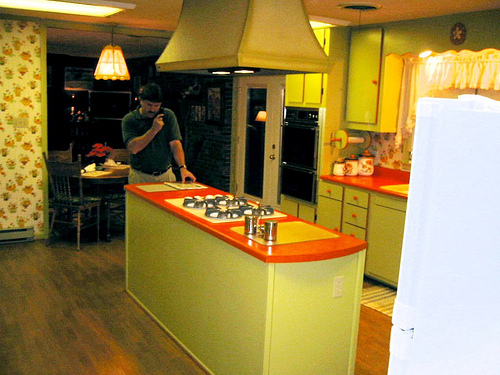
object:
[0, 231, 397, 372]
ground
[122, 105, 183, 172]
shirt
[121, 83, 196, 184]
man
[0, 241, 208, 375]
floor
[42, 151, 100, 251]
chair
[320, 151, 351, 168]
ground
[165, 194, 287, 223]
stove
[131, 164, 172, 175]
black belt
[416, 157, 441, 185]
ground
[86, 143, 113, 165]
flowers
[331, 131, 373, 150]
holder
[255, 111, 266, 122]
lights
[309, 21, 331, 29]
lights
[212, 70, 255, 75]
lights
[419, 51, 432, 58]
lights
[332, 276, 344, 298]
outlet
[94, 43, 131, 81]
lamp shade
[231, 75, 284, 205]
whiteb backdoor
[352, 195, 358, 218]
knob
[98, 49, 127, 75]
light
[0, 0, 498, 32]
ceiling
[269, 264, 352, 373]
wall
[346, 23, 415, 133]
cabinet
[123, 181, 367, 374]
island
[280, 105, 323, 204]
double oven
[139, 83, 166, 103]
black hair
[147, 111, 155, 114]
mustache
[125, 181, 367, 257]
counter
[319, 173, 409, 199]
counter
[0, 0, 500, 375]
kitchen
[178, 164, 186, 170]
wristwatch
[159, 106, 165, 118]
cell phone